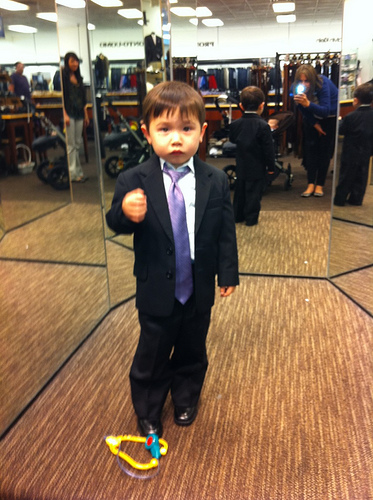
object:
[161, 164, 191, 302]
tie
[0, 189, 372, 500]
carpet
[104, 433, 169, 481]
toy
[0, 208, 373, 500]
ground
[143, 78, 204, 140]
hair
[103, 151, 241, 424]
suit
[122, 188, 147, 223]
hand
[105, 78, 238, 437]
boy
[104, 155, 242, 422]
tuxedo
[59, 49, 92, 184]
reflection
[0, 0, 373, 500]
room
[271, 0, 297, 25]
lights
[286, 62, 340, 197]
woman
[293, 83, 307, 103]
camera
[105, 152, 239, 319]
jacket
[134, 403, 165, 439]
shoes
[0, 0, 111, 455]
panel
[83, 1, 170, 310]
panel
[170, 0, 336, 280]
panel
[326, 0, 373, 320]
panel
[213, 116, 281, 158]
stroller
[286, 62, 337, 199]
reflection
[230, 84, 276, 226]
reflection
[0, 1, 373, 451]
mirror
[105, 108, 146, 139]
stroller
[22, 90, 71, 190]
stroller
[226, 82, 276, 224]
boy w/blacksuit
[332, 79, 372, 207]
boy w/blacksuit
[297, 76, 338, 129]
sweater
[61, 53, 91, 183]
woman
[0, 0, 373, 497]
store